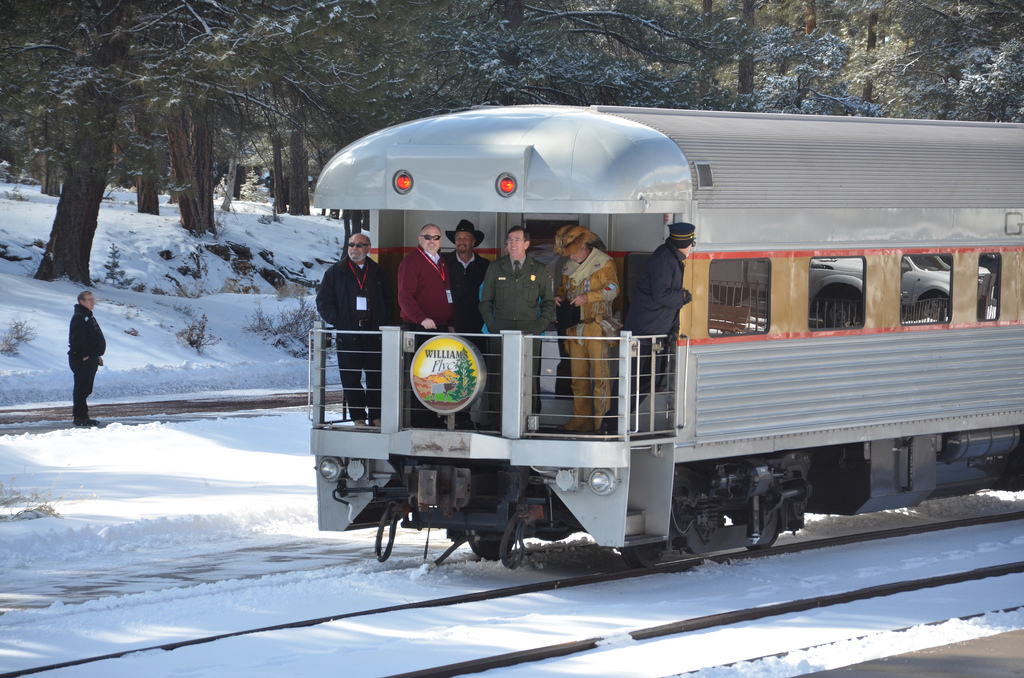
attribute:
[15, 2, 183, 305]
leaves — green 